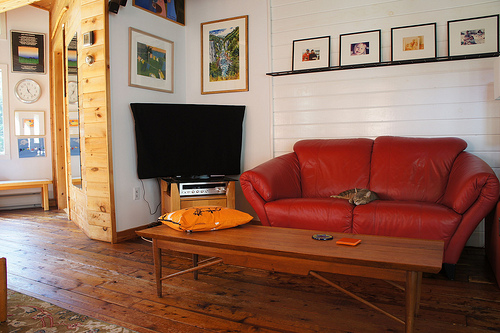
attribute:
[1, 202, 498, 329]
floor — wood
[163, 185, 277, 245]
pillow — orange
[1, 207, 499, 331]
flooring — wood, wooden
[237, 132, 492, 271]
couch — red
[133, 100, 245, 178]
tv screen — flat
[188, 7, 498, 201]
wall — white